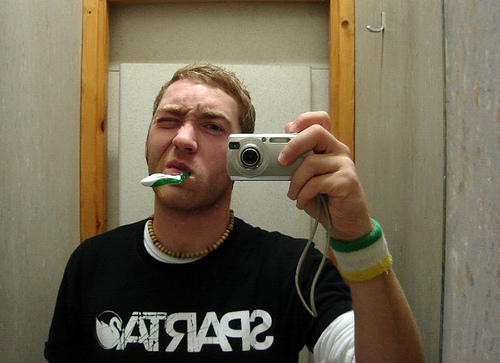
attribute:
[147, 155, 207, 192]
toothbrush — green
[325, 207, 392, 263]
wristband — green, white, yellow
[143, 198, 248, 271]
necklace — brown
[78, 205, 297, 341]
shirt — black, white, writing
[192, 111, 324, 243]
camera — held, silver, gray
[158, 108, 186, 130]
eye — closed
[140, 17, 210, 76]
door — wood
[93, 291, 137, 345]
logo — swan, white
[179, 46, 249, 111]
hair — short, brown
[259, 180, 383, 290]
man — taking selfie, talking selfie, wearing, standing, holding, frowning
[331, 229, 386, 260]
band — green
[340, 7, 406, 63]
handle — hanging